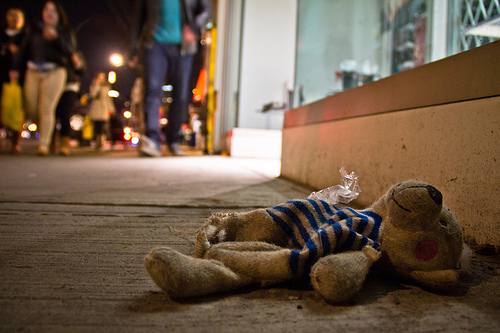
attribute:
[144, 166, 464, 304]
teddy bear — ripped, torn apart, flattened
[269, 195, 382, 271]
stripes — blue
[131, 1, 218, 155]
person — walking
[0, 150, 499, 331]
sidewalk — rough, concrete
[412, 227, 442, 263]
cheek — red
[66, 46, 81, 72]
bag — yellow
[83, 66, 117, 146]
woman — on phone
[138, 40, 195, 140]
pants — denim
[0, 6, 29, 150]
person — walking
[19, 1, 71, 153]
person — walking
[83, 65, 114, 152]
person — walking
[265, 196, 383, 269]
shirt — blue, white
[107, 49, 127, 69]
light — shining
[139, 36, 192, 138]
jeans — blue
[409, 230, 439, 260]
cheek — pink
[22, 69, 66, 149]
pants — tan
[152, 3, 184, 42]
shirt — blue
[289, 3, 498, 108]
window — glass, store front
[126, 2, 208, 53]
jacket — black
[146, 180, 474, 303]
teddy bear — brown, blue, ripped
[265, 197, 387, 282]
shirt — blue, gray, striped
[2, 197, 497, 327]
slab — gray, cement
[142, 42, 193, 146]
jeans — blue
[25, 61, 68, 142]
pants — khaki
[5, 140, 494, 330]
pavement — brown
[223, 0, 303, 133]
side — gray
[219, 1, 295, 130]
side — gray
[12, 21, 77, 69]
sweater — brown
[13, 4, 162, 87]
sky — dark, blue